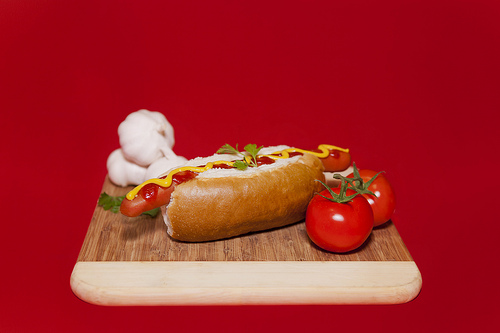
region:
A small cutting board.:
[66, 237, 419, 304]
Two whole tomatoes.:
[300, 161, 395, 251]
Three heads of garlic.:
[95, 105, 171, 182]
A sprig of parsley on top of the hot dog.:
[211, 138, 263, 171]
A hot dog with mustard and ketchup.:
[116, 140, 346, 240]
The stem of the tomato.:
[315, 176, 362, 204]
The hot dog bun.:
[166, 165, 321, 235]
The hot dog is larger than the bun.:
[117, 145, 354, 240]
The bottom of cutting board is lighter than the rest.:
[70, 236, 425, 301]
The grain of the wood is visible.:
[70, 232, 421, 303]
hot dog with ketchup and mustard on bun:
[117, 185, 157, 216]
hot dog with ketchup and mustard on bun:
[163, 178, 203, 199]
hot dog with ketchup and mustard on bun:
[184, 163, 216, 192]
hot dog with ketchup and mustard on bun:
[221, 155, 268, 180]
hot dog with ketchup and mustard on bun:
[249, 145, 289, 170]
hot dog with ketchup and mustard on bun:
[280, 144, 311, 171]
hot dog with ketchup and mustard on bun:
[304, 141, 331, 168]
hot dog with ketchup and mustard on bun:
[319, 144, 339, 165]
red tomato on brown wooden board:
[306, 181, 372, 261]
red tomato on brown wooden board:
[348, 166, 397, 224]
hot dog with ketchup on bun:
[167, 142, 297, 235]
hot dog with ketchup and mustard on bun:
[126, 175, 186, 205]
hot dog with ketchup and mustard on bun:
[203, 154, 229, 184]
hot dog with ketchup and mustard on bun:
[241, 146, 306, 180]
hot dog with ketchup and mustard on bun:
[291, 149, 314, 177]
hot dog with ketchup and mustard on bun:
[303, 135, 362, 172]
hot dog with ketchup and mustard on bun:
[164, 166, 238, 224]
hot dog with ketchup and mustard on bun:
[226, 142, 267, 196]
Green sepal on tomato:
[310, 172, 360, 204]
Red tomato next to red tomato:
[305, 185, 375, 252]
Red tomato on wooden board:
[305, 180, 370, 254]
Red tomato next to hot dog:
[300, 181, 370, 251]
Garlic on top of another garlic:
[115, 105, 170, 160]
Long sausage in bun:
[115, 140, 347, 217]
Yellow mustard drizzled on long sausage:
[120, 136, 346, 203]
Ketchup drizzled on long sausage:
[126, 138, 344, 218]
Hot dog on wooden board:
[110, 135, 355, 240]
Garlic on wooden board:
[105, 142, 146, 187]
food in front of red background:
[4, 2, 490, 328]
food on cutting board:
[70, 111, 424, 308]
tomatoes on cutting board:
[303, 163, 395, 252]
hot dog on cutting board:
[117, 142, 349, 242]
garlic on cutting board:
[100, 102, 195, 195]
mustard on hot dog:
[115, 144, 347, 208]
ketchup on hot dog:
[112, 139, 344, 204]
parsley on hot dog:
[219, 137, 266, 174]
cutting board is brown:
[50, 105, 427, 311]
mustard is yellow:
[131, 141, 347, 202]